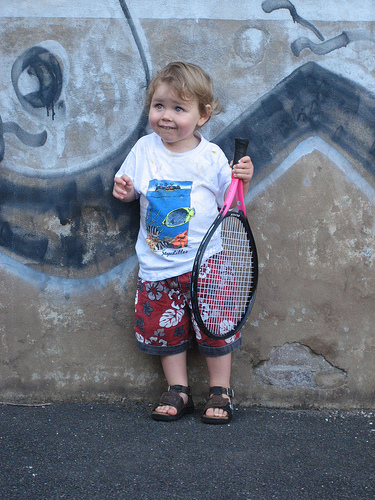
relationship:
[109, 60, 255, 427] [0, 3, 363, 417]
boy standing against wall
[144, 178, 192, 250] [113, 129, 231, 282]
artwork on front of shirt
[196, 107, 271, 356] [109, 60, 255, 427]
racket held boy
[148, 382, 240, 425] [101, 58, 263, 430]
sandals on child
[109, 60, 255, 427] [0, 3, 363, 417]
boy standing wall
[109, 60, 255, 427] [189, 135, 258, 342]
boy holding racket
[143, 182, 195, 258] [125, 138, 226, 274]
fish printed shirt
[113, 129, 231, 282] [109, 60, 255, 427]
shirt worn boy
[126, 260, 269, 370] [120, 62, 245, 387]
shorts worn child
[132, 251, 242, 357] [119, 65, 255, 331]
shorts worn child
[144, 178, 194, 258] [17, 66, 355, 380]
artwork painted on wall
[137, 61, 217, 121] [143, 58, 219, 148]
hair on top head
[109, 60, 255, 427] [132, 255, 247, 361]
boy wearing shorts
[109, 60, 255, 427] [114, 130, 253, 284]
boy wearing shirt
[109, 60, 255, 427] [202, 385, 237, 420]
boy wearing sandals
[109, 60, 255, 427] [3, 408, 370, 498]
boy standing floor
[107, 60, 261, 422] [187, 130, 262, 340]
boy holding racket